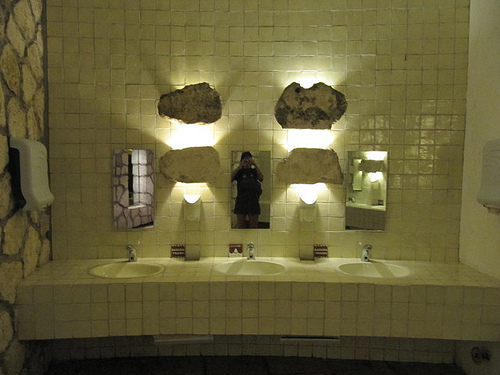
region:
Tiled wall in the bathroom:
[41, 0, 471, 264]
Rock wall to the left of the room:
[1, 1, 52, 372]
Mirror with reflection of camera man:
[226, 146, 276, 234]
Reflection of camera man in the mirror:
[229, 148, 266, 231]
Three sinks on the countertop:
[82, 236, 417, 291]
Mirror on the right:
[343, 146, 393, 236]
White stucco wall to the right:
[458, 1, 497, 291]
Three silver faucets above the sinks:
[115, 239, 385, 264]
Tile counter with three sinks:
[11, 251, 497, 342]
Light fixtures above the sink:
[154, 76, 351, 231]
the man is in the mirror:
[231, 148, 268, 230]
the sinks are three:
[77, 236, 439, 284]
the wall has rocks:
[11, 87, 47, 132]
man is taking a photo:
[237, 153, 274, 238]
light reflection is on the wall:
[403, 118, 470, 205]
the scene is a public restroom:
[3, 78, 488, 374]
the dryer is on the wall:
[13, 132, 75, 221]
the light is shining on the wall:
[164, 128, 334, 235]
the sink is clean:
[45, 259, 494, 345]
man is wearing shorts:
[231, 176, 279, 222]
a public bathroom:
[5, 22, 499, 357]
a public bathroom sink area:
[10, 27, 499, 334]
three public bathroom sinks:
[72, 134, 489, 359]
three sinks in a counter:
[74, 205, 493, 322]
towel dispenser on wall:
[4, 119, 82, 246]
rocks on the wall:
[140, 26, 386, 275]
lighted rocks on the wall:
[150, 34, 375, 254]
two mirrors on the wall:
[58, 87, 496, 317]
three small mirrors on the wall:
[91, 63, 491, 325]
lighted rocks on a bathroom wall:
[147, 59, 392, 247]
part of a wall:
[396, 200, 418, 242]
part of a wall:
[276, 215, 284, 234]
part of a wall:
[413, 210, 445, 244]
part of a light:
[293, 187, 339, 253]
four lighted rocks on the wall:
[100, 18, 447, 301]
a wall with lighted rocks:
[137, 39, 382, 228]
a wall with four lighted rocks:
[107, 19, 342, 237]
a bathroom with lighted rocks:
[54, 28, 499, 301]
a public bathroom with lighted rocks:
[32, 40, 495, 330]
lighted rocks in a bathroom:
[2, 6, 497, 251]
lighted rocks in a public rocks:
[19, 32, 494, 305]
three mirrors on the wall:
[69, 75, 487, 346]